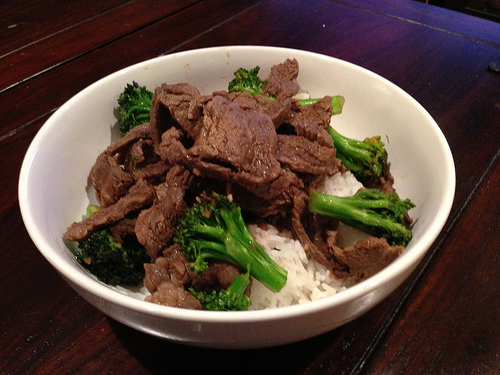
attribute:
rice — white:
[246, 223, 349, 312]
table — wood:
[391, 20, 480, 124]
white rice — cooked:
[243, 222, 348, 310]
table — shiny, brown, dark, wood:
[0, 2, 497, 371]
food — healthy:
[62, 65, 419, 305]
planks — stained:
[3, 6, 496, 374]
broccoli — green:
[177, 198, 279, 297]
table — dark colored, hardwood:
[401, 33, 458, 90]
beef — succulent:
[132, 132, 362, 198]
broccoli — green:
[113, 79, 155, 131]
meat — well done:
[70, 83, 338, 238]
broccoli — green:
[73, 223, 145, 293]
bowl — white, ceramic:
[11, 42, 461, 349]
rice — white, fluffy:
[231, 159, 381, 305]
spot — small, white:
[323, 20, 326, 30]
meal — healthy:
[78, 71, 398, 301]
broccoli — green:
[123, 140, 316, 290]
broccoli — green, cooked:
[171, 195, 298, 297]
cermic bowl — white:
[34, 49, 434, 294]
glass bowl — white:
[113, 76, 428, 293]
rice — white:
[247, 168, 362, 310]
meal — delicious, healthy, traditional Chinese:
[68, 50, 419, 317]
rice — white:
[295, 237, 309, 263]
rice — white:
[308, 280, 322, 296]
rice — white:
[269, 295, 279, 308]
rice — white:
[265, 233, 285, 243]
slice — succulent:
[165, 121, 252, 199]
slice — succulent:
[171, 103, 249, 223]